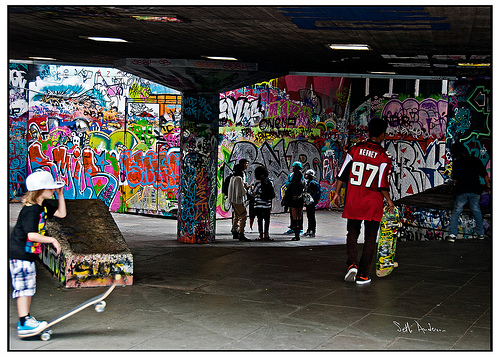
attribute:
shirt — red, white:
[339, 142, 390, 219]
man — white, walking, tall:
[328, 111, 405, 286]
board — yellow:
[373, 200, 408, 278]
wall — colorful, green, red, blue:
[18, 60, 493, 226]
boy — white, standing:
[15, 166, 72, 333]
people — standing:
[225, 143, 326, 239]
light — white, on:
[322, 42, 375, 55]